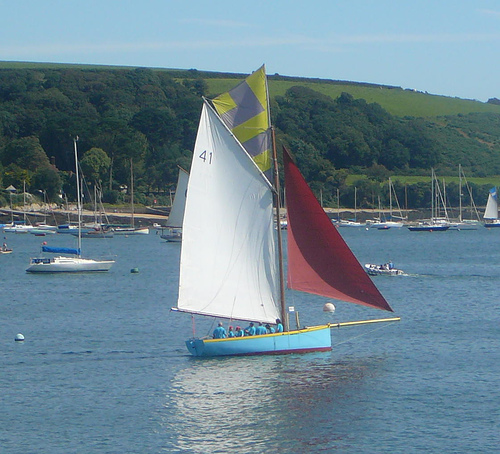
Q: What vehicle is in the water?
A: Boat.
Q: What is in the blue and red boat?
A: Group of people.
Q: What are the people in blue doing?
A: Sailing.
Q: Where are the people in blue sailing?
A: On a lake.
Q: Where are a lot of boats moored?
A: At the shore.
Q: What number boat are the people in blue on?
A: 41.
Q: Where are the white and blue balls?
A: On the lake.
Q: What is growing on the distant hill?
A: Grass and trees.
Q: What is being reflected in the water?
A: Boat 41.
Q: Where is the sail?
A: On the boat.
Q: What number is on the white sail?
A: 41.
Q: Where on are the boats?
A: In the water.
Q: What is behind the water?
A: Hill with trees.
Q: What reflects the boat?
A: The water.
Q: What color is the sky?
A: Blue.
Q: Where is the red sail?
A: On the boat.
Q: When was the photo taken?
A: Daytime.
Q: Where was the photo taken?
A: The lake.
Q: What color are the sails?
A: Red, White, Green and Gray.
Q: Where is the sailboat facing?
A: To the right.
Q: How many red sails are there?
A: One.